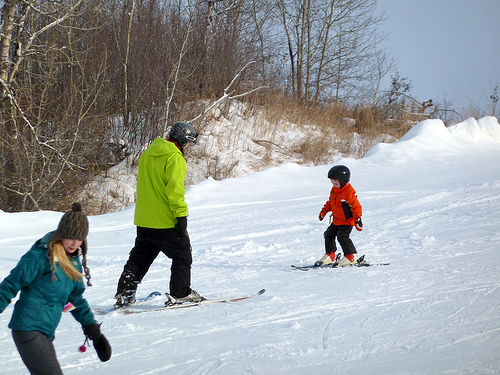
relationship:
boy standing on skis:
[318, 164, 363, 261] [292, 258, 392, 270]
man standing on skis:
[115, 120, 198, 300] [97, 286, 266, 315]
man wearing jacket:
[115, 120, 198, 300] [134, 136, 189, 230]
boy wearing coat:
[318, 164, 363, 261] [320, 183, 362, 225]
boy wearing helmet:
[318, 164, 363, 261] [327, 163, 350, 188]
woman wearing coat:
[1, 202, 112, 374] [1, 229, 98, 332]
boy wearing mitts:
[318, 164, 363, 261] [317, 209, 363, 233]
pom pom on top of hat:
[70, 200, 83, 213] [47, 201, 94, 287]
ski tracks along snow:
[4, 184, 497, 373] [1, 115, 499, 374]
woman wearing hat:
[1, 202, 112, 374] [47, 201, 94, 287]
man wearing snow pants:
[115, 120, 198, 300] [116, 225, 192, 299]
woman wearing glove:
[1, 202, 112, 374] [83, 320, 112, 362]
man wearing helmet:
[115, 120, 198, 300] [168, 120, 197, 149]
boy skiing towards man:
[318, 164, 363, 261] [115, 120, 198, 300]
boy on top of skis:
[318, 164, 363, 261] [292, 258, 392, 270]